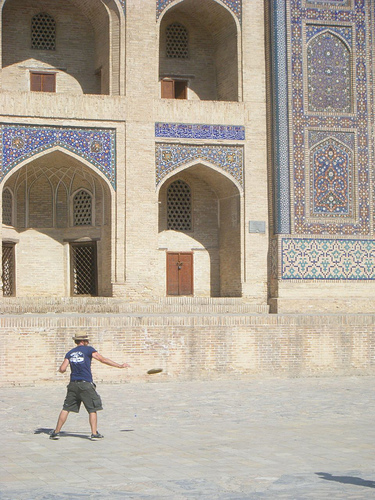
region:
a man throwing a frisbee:
[48, 329, 163, 442]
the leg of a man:
[53, 402, 70, 433]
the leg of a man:
[87, 410, 99, 435]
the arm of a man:
[90, 350, 129, 368]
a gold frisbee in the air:
[146, 363, 163, 375]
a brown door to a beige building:
[164, 248, 195, 296]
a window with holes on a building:
[165, 175, 194, 232]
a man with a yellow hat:
[70, 331, 90, 341]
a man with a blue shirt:
[63, 343, 98, 382]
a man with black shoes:
[47, 430, 104, 442]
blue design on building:
[287, 266, 295, 274]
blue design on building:
[286, 250, 295, 257]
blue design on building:
[282, 272, 289, 278]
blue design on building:
[289, 273, 295, 277]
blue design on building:
[293, 272, 301, 278]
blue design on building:
[304, 271, 311, 278]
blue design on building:
[310, 272, 316, 277]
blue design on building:
[316, 271, 321, 277]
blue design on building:
[308, 266, 318, 274]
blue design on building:
[332, 263, 340, 274]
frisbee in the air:
[150, 363, 163, 378]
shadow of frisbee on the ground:
[111, 422, 131, 434]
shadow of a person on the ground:
[308, 465, 373, 491]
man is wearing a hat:
[65, 330, 95, 340]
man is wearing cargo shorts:
[60, 379, 108, 412]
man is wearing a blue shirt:
[63, 344, 96, 376]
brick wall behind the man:
[105, 326, 193, 383]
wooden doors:
[158, 247, 203, 300]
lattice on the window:
[69, 239, 101, 298]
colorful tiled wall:
[281, 170, 344, 280]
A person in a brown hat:
[49, 331, 129, 438]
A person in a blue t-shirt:
[49, 331, 130, 438]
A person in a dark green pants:
[49, 330, 130, 441]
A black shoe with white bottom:
[90, 431, 102, 438]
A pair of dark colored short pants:
[64, 380, 103, 413]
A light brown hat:
[72, 330, 89, 339]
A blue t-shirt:
[65, 345, 96, 380]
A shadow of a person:
[315, 470, 374, 488]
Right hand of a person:
[121, 362, 129, 367]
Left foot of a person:
[47, 431, 60, 438]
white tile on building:
[328, 194, 333, 202]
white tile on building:
[328, 171, 333, 177]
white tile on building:
[325, 84, 331, 92]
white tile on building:
[325, 68, 331, 74]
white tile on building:
[324, 50, 332, 55]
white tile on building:
[316, 41, 321, 46]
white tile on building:
[314, 145, 319, 150]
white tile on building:
[336, 142, 341, 147]